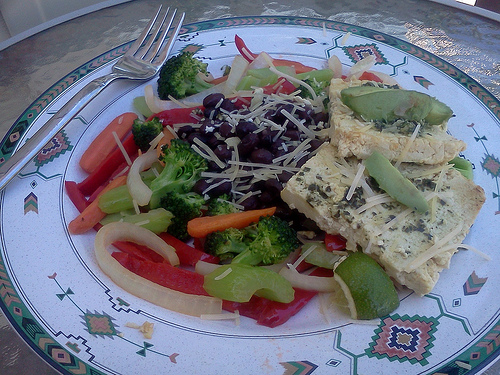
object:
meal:
[57, 32, 492, 325]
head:
[112, 0, 185, 79]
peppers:
[76, 142, 323, 339]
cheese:
[187, 83, 492, 274]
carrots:
[63, 111, 140, 235]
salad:
[66, 49, 486, 326]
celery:
[199, 262, 298, 306]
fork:
[1, 0, 185, 186]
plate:
[0, 14, 497, 373]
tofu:
[282, 78, 486, 295]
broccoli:
[229, 213, 298, 270]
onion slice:
[89, 220, 226, 318]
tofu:
[275, 126, 487, 302]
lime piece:
[333, 249, 404, 322]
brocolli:
[154, 39, 220, 101]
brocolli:
[128, 108, 167, 144]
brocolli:
[147, 138, 207, 197]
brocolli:
[207, 192, 249, 256]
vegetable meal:
[63, 33, 489, 331]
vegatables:
[64, 35, 488, 333]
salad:
[195, 108, 336, 208]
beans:
[196, 92, 323, 195]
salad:
[158, 129, 328, 276]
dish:
[60, 51, 483, 336]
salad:
[141, 75, 451, 262]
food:
[64, 37, 485, 310]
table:
[5, 3, 484, 120]